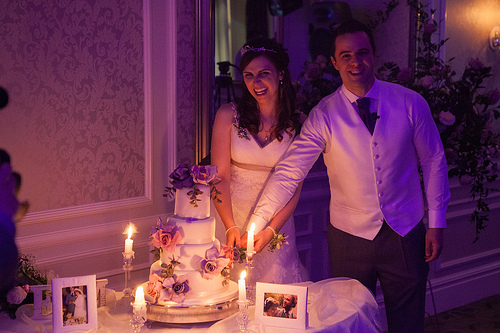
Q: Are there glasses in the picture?
A: No, there are no glasses.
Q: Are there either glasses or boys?
A: No, there are no glasses or boys.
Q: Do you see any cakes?
A: Yes, there is a cake.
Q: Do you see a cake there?
A: Yes, there is a cake.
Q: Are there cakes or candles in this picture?
A: Yes, there is a cake.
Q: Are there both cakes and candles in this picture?
A: Yes, there are both a cake and a candle.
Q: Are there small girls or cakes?
A: Yes, there is a small cake.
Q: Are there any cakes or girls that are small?
A: Yes, the cake is small.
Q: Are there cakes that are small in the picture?
A: Yes, there is a small cake.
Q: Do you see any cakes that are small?
A: Yes, there is a small cake.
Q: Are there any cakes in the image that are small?
A: Yes, there is a cake that is small.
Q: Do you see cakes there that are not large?
A: Yes, there is a small cake.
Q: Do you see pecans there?
A: No, there are no pecans.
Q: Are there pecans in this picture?
A: No, there are no pecans.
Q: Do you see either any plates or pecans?
A: No, there are no pecans or plates.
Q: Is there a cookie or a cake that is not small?
A: No, there is a cake but it is small.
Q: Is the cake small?
A: Yes, the cake is small.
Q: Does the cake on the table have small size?
A: Yes, the cake is small.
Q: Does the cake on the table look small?
A: Yes, the cake is small.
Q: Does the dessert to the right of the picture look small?
A: Yes, the cake is small.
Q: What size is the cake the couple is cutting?
A: The cake is small.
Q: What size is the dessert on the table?
A: The cake is small.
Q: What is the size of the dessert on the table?
A: The cake is small.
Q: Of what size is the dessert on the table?
A: The cake is small.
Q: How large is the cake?
A: The cake is small.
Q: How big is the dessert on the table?
A: The cake is small.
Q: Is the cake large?
A: No, the cake is small.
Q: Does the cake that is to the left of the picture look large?
A: No, the cake is small.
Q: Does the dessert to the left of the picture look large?
A: No, the cake is small.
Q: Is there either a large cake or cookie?
A: No, there is a cake but it is small.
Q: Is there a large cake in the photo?
A: No, there is a cake but it is small.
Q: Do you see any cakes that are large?
A: No, there is a cake but it is small.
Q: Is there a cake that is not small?
A: No, there is a cake but it is small.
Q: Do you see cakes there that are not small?
A: No, there is a cake but it is small.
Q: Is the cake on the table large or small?
A: The cake is small.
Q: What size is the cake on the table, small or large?
A: The cake is small.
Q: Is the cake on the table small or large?
A: The cake is small.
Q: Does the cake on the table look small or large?
A: The cake is small.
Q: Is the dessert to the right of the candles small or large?
A: The cake is small.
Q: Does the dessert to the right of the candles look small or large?
A: The cake is small.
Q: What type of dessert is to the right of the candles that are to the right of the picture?
A: The dessert is a cake.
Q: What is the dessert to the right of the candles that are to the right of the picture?
A: The dessert is a cake.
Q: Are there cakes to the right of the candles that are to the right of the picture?
A: Yes, there is a cake to the right of the candles.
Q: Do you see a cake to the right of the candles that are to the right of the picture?
A: Yes, there is a cake to the right of the candles.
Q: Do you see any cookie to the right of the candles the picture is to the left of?
A: No, there is a cake to the right of the candles.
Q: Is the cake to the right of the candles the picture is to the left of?
A: Yes, the cake is to the right of the candles.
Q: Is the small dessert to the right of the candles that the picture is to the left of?
A: Yes, the cake is to the right of the candles.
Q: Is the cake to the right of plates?
A: No, the cake is to the right of the candles.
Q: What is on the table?
A: The cake is on the table.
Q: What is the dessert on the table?
A: The dessert is a cake.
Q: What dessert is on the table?
A: The dessert is a cake.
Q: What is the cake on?
A: The cake is on the table.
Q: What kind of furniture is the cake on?
A: The cake is on the table.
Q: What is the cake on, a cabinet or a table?
A: The cake is on a table.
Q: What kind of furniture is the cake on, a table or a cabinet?
A: The cake is on a table.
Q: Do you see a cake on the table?
A: Yes, there is a cake on the table.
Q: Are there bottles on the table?
A: No, there is a cake on the table.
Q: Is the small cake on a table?
A: Yes, the cake is on a table.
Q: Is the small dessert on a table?
A: Yes, the cake is on a table.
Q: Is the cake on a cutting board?
A: No, the cake is on a table.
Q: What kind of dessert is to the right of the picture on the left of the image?
A: The dessert is a cake.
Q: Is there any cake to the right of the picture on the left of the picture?
A: Yes, there is a cake to the right of the picture.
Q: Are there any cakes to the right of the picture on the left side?
A: Yes, there is a cake to the right of the picture.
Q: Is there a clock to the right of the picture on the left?
A: No, there is a cake to the right of the picture.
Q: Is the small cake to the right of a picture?
A: Yes, the cake is to the right of a picture.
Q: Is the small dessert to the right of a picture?
A: Yes, the cake is to the right of a picture.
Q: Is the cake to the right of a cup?
A: No, the cake is to the right of a picture.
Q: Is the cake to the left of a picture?
A: Yes, the cake is to the left of a picture.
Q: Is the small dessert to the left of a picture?
A: Yes, the cake is to the left of a picture.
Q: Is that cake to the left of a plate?
A: No, the cake is to the left of a picture.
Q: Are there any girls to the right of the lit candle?
A: No, there is a cake to the right of the candle.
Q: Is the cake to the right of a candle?
A: Yes, the cake is to the right of a candle.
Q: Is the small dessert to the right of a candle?
A: Yes, the cake is to the right of a candle.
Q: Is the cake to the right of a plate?
A: No, the cake is to the right of a candle.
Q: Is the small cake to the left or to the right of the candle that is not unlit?
A: The cake is to the right of the candle.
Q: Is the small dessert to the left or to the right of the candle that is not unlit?
A: The cake is to the right of the candle.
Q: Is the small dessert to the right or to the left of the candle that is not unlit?
A: The cake is to the right of the candle.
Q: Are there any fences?
A: No, there are no fences.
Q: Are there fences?
A: No, there are no fences.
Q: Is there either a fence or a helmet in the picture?
A: No, there are no fences or helmets.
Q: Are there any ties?
A: Yes, there is a tie.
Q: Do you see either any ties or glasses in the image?
A: Yes, there is a tie.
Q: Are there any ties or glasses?
A: Yes, there is a tie.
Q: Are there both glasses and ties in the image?
A: No, there is a tie but no glasses.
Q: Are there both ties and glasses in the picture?
A: No, there is a tie but no glasses.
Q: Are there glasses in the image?
A: No, there are no glasses.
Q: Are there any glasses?
A: No, there are no glasses.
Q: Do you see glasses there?
A: No, there are no glasses.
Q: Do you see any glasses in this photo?
A: No, there are no glasses.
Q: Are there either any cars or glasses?
A: No, there are no glasses or cars.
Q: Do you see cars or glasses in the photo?
A: No, there are no glasses or cars.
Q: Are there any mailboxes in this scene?
A: No, there are no mailboxes.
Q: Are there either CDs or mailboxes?
A: No, there are no mailboxes or cds.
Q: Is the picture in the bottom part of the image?
A: Yes, the picture is in the bottom of the image.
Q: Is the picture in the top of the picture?
A: No, the picture is in the bottom of the image.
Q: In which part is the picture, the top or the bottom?
A: The picture is in the bottom of the image.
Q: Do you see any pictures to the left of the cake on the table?
A: Yes, there is a picture to the left of the cake.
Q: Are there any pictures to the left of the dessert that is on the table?
A: Yes, there is a picture to the left of the cake.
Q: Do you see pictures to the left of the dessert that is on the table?
A: Yes, there is a picture to the left of the cake.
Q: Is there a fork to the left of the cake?
A: No, there is a picture to the left of the cake.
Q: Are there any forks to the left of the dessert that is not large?
A: No, there is a picture to the left of the cake.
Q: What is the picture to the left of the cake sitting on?
A: The picture is sitting on the table.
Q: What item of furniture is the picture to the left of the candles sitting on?
A: The picture is sitting on the table.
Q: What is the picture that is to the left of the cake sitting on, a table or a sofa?
A: The picture is sitting on a table.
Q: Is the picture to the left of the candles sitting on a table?
A: Yes, the picture is sitting on a table.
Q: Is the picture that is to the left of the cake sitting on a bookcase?
A: No, the picture is sitting on a table.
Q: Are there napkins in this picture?
A: No, there are no napkins.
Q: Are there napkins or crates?
A: No, there are no napkins or crates.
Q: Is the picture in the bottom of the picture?
A: Yes, the picture is in the bottom of the image.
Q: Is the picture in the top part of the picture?
A: No, the picture is in the bottom of the image.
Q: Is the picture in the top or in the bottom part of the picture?
A: The picture is in the bottom of the image.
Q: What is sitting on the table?
A: The picture is sitting on the table.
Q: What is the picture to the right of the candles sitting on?
A: The picture is sitting on the table.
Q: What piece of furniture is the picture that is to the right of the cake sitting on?
A: The picture is sitting on the table.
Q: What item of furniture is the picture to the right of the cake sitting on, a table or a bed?
A: The picture is sitting on a table.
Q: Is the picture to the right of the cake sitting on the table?
A: Yes, the picture is sitting on the table.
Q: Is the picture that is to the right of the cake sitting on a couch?
A: No, the picture is sitting on the table.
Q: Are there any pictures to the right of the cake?
A: Yes, there is a picture to the right of the cake.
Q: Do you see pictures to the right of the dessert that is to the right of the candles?
A: Yes, there is a picture to the right of the cake.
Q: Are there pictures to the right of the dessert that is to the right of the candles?
A: Yes, there is a picture to the right of the cake.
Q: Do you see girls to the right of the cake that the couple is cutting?
A: No, there is a picture to the right of the cake.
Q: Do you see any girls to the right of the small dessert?
A: No, there is a picture to the right of the cake.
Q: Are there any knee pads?
A: No, there are no knee pads.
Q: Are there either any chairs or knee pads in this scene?
A: No, there are no knee pads or chairs.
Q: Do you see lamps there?
A: No, there are no lamps.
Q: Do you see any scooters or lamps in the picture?
A: No, there are no lamps or scooters.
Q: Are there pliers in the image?
A: No, there are no pliers.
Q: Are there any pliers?
A: No, there are no pliers.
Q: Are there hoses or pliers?
A: No, there are no pliers or hoses.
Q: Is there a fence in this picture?
A: No, there are no fences.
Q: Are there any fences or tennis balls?
A: No, there are no fences or tennis balls.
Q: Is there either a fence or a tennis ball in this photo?
A: No, there are no fences or tennis balls.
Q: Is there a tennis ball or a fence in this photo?
A: No, there are no fences or tennis balls.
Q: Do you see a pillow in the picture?
A: No, there are no pillows.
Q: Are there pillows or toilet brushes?
A: No, there are no pillows or toilet brushes.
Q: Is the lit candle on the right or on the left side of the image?
A: The candle is on the left of the image.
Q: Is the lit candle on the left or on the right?
A: The candle is on the left of the image.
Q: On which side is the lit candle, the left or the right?
A: The candle is on the left of the image.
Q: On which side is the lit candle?
A: The candle is on the left of the image.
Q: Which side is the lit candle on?
A: The candle is on the left of the image.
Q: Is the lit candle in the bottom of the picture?
A: Yes, the candle is in the bottom of the image.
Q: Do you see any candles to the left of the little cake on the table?
A: Yes, there is a candle to the left of the cake.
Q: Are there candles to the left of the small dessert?
A: Yes, there is a candle to the left of the cake.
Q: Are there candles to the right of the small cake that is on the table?
A: No, the candle is to the left of the cake.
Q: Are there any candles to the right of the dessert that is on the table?
A: No, the candle is to the left of the cake.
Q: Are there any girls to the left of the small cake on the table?
A: No, there is a candle to the left of the cake.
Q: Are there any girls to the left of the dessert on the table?
A: No, there is a candle to the left of the cake.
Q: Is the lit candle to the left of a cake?
A: Yes, the candle is to the left of a cake.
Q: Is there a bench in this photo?
A: No, there are no benches.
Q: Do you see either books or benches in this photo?
A: No, there are no benches or books.